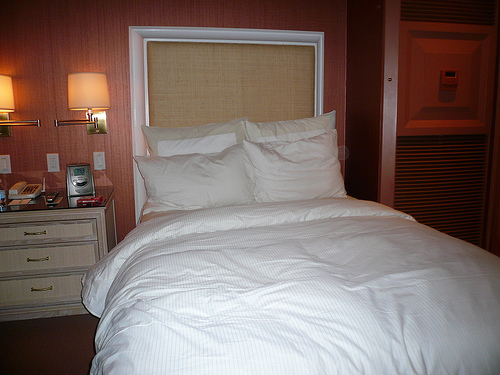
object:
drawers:
[0, 270, 88, 312]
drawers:
[0, 238, 98, 275]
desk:
[0, 185, 118, 318]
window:
[127, 24, 324, 224]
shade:
[146, 43, 316, 126]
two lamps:
[0, 69, 111, 139]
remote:
[44, 188, 59, 202]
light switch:
[92, 149, 106, 172]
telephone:
[3, 178, 43, 202]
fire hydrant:
[84, 108, 105, 134]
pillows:
[140, 117, 246, 157]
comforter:
[80, 197, 499, 374]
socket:
[44, 151, 59, 173]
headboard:
[130, 25, 325, 225]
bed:
[80, 110, 499, 374]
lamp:
[1, 71, 40, 136]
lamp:
[53, 70, 109, 135]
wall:
[1, 1, 500, 246]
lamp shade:
[66, 71, 108, 109]